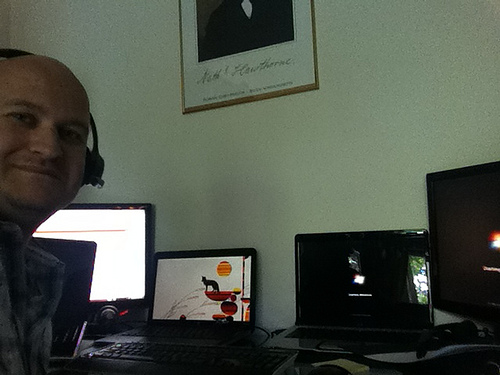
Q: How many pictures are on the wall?
A: One.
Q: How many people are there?
A: One.